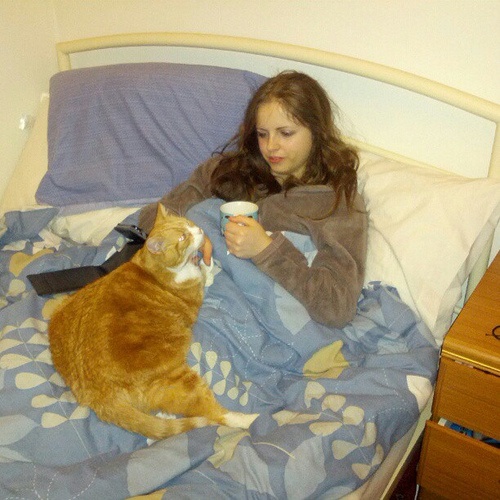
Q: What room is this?
A: It is a bedroom.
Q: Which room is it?
A: It is a bedroom.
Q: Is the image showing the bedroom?
A: Yes, it is showing the bedroom.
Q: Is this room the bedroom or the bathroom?
A: It is the bedroom.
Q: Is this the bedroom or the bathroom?
A: It is the bedroom.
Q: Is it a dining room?
A: No, it is a bedroom.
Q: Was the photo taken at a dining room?
A: No, the picture was taken in a bedroom.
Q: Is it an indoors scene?
A: Yes, it is indoors.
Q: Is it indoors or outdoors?
A: It is indoors.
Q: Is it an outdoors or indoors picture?
A: It is indoors.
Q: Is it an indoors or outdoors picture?
A: It is indoors.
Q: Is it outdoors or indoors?
A: It is indoors.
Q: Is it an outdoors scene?
A: No, it is indoors.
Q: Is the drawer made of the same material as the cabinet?
A: Yes, both the drawer and the cabinet are made of wood.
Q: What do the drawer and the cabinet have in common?
A: The material, both the drawer and the cabinet are wooden.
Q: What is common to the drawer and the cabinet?
A: The material, both the drawer and the cabinet are wooden.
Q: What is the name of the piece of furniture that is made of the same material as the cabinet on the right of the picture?
A: The piece of furniture is a drawer.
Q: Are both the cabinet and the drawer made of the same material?
A: Yes, both the cabinet and the drawer are made of wood.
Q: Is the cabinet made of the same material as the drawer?
A: Yes, both the cabinet and the drawer are made of wood.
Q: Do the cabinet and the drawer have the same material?
A: Yes, both the cabinet and the drawer are made of wood.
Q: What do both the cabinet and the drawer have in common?
A: The material, both the cabinet and the drawer are wooden.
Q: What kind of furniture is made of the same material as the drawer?
A: The cabinet is made of the same material as the drawer.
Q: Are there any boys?
A: No, there are no boys.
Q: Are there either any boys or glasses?
A: No, there are no boys or glasses.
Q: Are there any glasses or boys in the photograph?
A: No, there are no boys or glasses.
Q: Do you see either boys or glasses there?
A: No, there are no boys or glasses.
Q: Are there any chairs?
A: No, there are no chairs.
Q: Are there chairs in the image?
A: No, there are no chairs.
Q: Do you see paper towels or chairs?
A: No, there are no chairs or paper towels.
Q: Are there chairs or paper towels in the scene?
A: No, there are no chairs or paper towels.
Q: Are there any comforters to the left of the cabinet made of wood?
A: Yes, there is a comforter to the left of the cabinet.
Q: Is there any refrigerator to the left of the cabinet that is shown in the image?
A: No, there is a comforter to the left of the cabinet.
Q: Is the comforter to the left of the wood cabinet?
A: Yes, the comforter is to the left of the cabinet.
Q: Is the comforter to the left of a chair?
A: No, the comforter is to the left of the cabinet.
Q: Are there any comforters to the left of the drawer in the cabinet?
A: Yes, there is a comforter to the left of the drawer.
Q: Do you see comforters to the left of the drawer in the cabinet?
A: Yes, there is a comforter to the left of the drawer.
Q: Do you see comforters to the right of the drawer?
A: No, the comforter is to the left of the drawer.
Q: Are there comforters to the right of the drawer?
A: No, the comforter is to the left of the drawer.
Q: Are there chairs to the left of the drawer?
A: No, there is a comforter to the left of the drawer.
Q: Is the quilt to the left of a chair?
A: No, the quilt is to the left of the drawer.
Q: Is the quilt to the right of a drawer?
A: No, the quilt is to the left of a drawer.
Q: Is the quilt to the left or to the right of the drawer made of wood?
A: The quilt is to the left of the drawer.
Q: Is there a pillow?
A: Yes, there is a pillow.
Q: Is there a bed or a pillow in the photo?
A: Yes, there is a pillow.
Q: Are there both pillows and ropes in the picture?
A: No, there is a pillow but no ropes.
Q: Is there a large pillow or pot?
A: Yes, there is a large pillow.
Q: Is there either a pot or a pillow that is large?
A: Yes, the pillow is large.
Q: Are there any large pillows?
A: Yes, there is a large pillow.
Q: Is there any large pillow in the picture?
A: Yes, there is a large pillow.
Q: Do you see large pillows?
A: Yes, there is a large pillow.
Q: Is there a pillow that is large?
A: Yes, there is a pillow that is large.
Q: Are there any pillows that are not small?
A: Yes, there is a large pillow.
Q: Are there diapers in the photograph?
A: No, there are no diapers.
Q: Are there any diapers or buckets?
A: No, there are no diapers or buckets.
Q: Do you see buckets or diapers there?
A: No, there are no diapers or buckets.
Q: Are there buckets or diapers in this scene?
A: No, there are no diapers or buckets.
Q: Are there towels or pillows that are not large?
A: No, there is a pillow but it is large.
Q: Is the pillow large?
A: Yes, the pillow is large.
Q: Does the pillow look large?
A: Yes, the pillow is large.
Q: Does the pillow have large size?
A: Yes, the pillow is large.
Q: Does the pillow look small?
A: No, the pillow is large.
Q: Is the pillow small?
A: No, the pillow is large.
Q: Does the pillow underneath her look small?
A: No, the pillow is large.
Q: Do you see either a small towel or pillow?
A: No, there is a pillow but it is large.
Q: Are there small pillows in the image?
A: No, there is a pillow but it is large.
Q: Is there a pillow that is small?
A: No, there is a pillow but it is large.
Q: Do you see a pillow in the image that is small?
A: No, there is a pillow but it is large.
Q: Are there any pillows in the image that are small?
A: No, there is a pillow but it is large.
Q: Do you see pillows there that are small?
A: No, there is a pillow but it is large.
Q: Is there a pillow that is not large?
A: No, there is a pillow but it is large.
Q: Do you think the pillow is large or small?
A: The pillow is large.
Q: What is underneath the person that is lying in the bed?
A: The pillow is underneath the woman.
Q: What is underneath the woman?
A: The pillow is underneath the woman.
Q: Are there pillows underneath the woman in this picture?
A: Yes, there is a pillow underneath the woman.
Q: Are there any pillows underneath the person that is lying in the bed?
A: Yes, there is a pillow underneath the woman.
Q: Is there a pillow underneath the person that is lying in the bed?
A: Yes, there is a pillow underneath the woman.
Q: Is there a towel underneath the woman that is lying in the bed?
A: No, there is a pillow underneath the woman.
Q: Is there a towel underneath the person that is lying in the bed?
A: No, there is a pillow underneath the woman.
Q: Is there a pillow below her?
A: Yes, there is a pillow below the woman.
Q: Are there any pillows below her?
A: Yes, there is a pillow below the woman.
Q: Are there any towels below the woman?
A: No, there is a pillow below the woman.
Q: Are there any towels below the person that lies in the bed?
A: No, there is a pillow below the woman.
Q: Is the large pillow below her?
A: Yes, the pillow is below the woman.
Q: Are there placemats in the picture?
A: No, there are no placemats.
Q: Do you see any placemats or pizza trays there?
A: No, there are no placemats or pizza trays.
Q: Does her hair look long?
A: Yes, the hair is long.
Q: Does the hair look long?
A: Yes, the hair is long.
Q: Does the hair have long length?
A: Yes, the hair is long.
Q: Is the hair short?
A: No, the hair is long.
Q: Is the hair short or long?
A: The hair is long.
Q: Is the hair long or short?
A: The hair is long.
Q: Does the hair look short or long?
A: The hair is long.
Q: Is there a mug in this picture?
A: Yes, there is a mug.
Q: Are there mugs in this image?
A: Yes, there is a mug.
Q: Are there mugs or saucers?
A: Yes, there is a mug.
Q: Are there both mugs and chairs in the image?
A: No, there is a mug but no chairs.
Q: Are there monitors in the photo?
A: No, there are no monitors.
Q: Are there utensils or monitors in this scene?
A: No, there are no monitors or utensils.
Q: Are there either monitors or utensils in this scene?
A: No, there are no monitors or utensils.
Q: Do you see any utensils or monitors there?
A: No, there are no monitors or utensils.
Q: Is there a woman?
A: Yes, there is a woman.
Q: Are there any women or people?
A: Yes, there is a woman.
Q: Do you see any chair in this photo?
A: No, there are no chairs.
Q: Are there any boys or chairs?
A: No, there are no chairs or boys.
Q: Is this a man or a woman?
A: This is a woman.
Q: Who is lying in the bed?
A: The woman is lying in the bed.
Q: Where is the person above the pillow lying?
A: The woman is lying in the bed.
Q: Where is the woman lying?
A: The woman is lying in the bed.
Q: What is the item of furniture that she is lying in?
A: The piece of furniture is a bed.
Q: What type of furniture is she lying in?
A: The woman is lying in the bed.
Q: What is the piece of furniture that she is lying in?
A: The piece of furniture is a bed.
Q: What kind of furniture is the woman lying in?
A: The woman is lying in the bed.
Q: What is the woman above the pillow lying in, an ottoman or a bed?
A: The woman is lying in a bed.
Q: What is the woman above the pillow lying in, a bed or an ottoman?
A: The woman is lying in a bed.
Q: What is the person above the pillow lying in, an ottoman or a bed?
A: The woman is lying in a bed.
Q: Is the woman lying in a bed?
A: Yes, the woman is lying in a bed.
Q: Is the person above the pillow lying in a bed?
A: Yes, the woman is lying in a bed.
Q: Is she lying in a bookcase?
A: No, the woman is lying in a bed.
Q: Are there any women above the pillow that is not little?
A: Yes, there is a woman above the pillow.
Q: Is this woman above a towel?
A: No, the woman is above the pillow.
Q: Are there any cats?
A: Yes, there is a cat.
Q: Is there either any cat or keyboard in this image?
A: Yes, there is a cat.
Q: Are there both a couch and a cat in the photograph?
A: No, there is a cat but no couches.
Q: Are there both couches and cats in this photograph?
A: No, there is a cat but no couches.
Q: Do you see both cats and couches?
A: No, there is a cat but no couches.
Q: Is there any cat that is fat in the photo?
A: Yes, there is a fat cat.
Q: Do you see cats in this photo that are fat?
A: Yes, there is a cat that is fat.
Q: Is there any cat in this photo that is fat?
A: Yes, there is a cat that is fat.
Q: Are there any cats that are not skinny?
A: Yes, there is a fat cat.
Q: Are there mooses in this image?
A: No, there are no mooses.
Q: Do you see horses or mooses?
A: No, there are no mooses or horses.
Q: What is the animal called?
A: The animal is a cat.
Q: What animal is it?
A: The animal is a cat.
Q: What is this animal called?
A: This is a cat.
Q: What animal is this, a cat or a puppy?
A: This is a cat.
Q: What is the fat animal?
A: The animal is a cat.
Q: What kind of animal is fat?
A: The animal is a cat.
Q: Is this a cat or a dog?
A: This is a cat.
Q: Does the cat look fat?
A: Yes, the cat is fat.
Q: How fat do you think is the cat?
A: The cat is fat.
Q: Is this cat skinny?
A: No, the cat is fat.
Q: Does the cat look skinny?
A: No, the cat is fat.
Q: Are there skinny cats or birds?
A: No, there is a cat but it is fat.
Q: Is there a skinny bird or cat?
A: No, there is a cat but it is fat.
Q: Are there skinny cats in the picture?
A: No, there is a cat but it is fat.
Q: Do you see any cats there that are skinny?
A: No, there is a cat but it is fat.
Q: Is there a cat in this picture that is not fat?
A: No, there is a cat but it is fat.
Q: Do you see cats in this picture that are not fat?
A: No, there is a cat but it is fat.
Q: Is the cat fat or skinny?
A: The cat is fat.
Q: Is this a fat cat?
A: Yes, this is a fat cat.